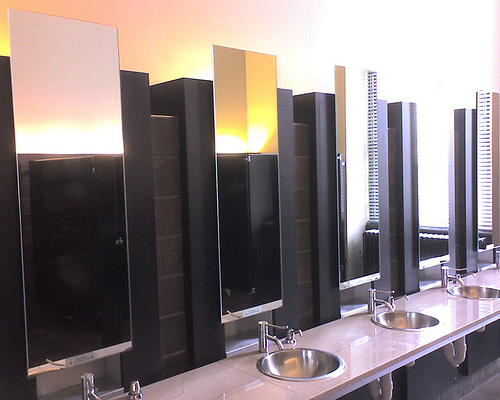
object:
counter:
[105, 266, 500, 400]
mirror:
[9, 6, 132, 378]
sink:
[257, 346, 345, 383]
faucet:
[258, 320, 289, 352]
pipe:
[444, 337, 469, 367]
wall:
[1, 56, 36, 400]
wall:
[149, 113, 194, 377]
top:
[8, 9, 120, 33]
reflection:
[217, 125, 276, 156]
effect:
[215, 46, 278, 153]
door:
[28, 155, 131, 366]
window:
[416, 104, 451, 231]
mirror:
[212, 44, 282, 326]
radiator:
[420, 233, 449, 263]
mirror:
[332, 64, 379, 292]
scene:
[0, 2, 500, 400]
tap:
[367, 287, 395, 314]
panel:
[153, 157, 183, 197]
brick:
[151, 114, 185, 157]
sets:
[364, 287, 442, 332]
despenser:
[286, 326, 304, 344]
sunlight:
[345, 69, 371, 241]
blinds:
[366, 70, 380, 223]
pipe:
[368, 367, 395, 400]